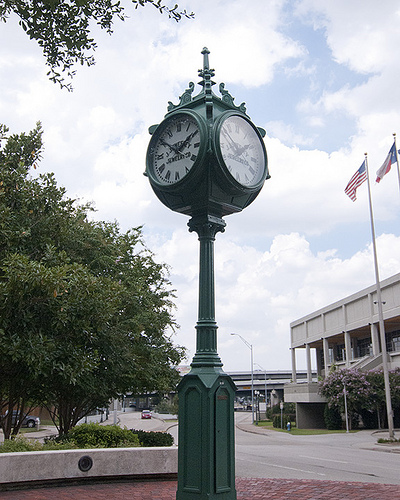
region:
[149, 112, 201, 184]
a clock on the pole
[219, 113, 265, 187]
clock face is white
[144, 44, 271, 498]
the pole is green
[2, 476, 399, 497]
bricks on the ground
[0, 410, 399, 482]
streets in the area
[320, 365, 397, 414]
tree with pink leaves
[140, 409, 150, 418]
red car is driving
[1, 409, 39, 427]
a truck is parked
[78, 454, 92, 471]
a hole in the wall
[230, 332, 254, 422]
a tall street light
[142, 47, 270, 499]
the green pole clock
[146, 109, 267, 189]
the clocks on the pole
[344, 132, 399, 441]
the flags on the poles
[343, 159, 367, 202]
the american flag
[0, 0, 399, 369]
the clouds in the sky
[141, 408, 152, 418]
the car on the road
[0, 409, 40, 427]
the car on the road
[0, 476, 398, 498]
the bricks on the ground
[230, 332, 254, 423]
the street light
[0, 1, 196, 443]
the trees near the pole clock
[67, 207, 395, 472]
view is in the street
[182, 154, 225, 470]
the clock pillar is metallic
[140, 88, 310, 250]
two clocks are fitted on the pillar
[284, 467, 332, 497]
the floor is made of bricks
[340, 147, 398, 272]
two flags next to the building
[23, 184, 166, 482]
a tree garden is besid he road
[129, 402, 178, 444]
a car is moving on the road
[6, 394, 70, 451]
the car is at park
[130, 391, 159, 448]
the car is red in color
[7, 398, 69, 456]
the car is gay in color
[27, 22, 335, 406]
this is an urban setting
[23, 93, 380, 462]
this is in a city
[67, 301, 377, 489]
this is a city street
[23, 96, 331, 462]
this is a courtyard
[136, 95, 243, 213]
this is a clock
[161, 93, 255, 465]
this is a street pole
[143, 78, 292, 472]
the pole is made of metal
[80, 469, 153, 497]
the ground here is brick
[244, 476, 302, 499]
the brick is red and brown